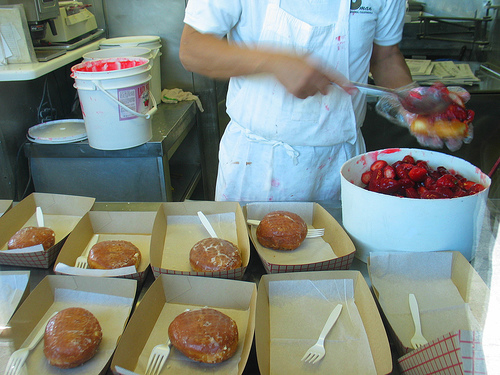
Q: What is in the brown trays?
A: Donuts.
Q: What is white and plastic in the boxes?
A: Forks.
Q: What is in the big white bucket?
A: Strawberries.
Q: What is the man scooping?
A: Fruit.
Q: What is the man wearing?
A: A white apron.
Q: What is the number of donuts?
A: Six.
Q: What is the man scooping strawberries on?
A: Donuts.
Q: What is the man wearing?
A: Plastic glove.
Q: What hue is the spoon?
A: Silver.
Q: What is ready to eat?
A: Donuts..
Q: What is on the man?
A: Apron.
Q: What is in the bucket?
A: Strawberries.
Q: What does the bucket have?
A: Handle.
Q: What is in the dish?
A: Donuts.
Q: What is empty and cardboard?
A: Dishes.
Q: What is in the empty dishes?
A: Forks.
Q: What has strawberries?
A: Tub.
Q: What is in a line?
A: Buckets.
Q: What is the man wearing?
A: Shirt.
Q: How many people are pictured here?
A: One.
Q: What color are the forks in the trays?
A: White.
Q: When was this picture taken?
A: Daytime.